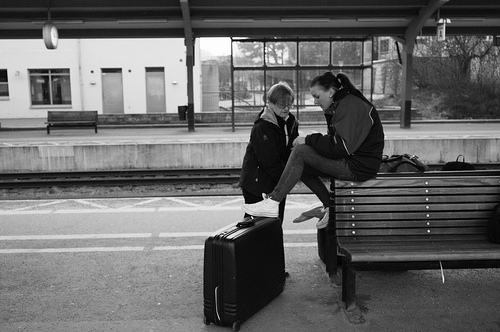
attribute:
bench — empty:
[42, 107, 100, 137]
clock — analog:
[43, 22, 57, 53]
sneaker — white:
[243, 192, 280, 217]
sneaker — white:
[316, 205, 330, 228]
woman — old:
[244, 82, 301, 215]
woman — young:
[290, 53, 380, 222]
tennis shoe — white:
[241, 191, 287, 220]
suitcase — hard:
[203, 214, 287, 330]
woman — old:
[242, 70, 382, 226]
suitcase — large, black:
[201, 219, 285, 325]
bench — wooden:
[325, 167, 499, 309]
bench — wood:
[337, 179, 498, 266]